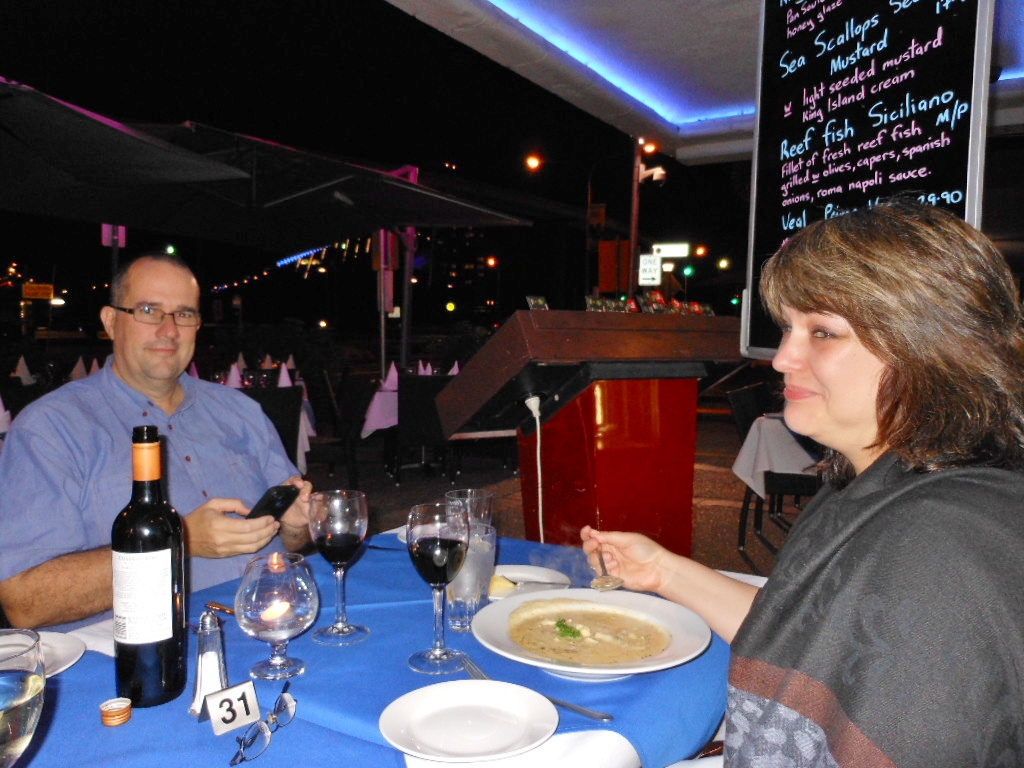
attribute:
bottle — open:
[105, 423, 197, 706]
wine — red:
[407, 536, 471, 587]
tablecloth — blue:
[302, 576, 400, 694]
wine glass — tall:
[400, 500, 483, 678]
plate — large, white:
[470, 588, 720, 684]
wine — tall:
[104, 414, 194, 708]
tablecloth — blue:
[164, 498, 678, 759]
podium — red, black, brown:
[414, 257, 759, 568]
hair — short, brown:
[770, 206, 1009, 464]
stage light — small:
[521, 149, 544, 179]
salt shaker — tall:
[180, 607, 234, 718]